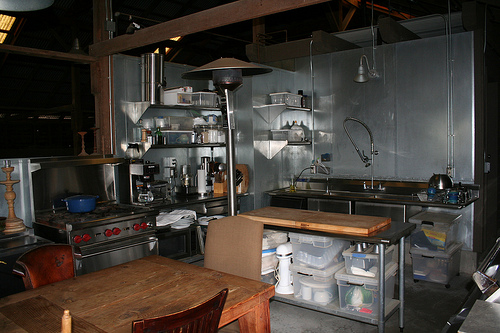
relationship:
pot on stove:
[58, 188, 107, 216] [50, 205, 148, 224]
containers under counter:
[265, 231, 379, 316] [254, 204, 412, 251]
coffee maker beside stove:
[124, 158, 168, 211] [50, 205, 148, 224]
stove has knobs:
[50, 205, 148, 224] [71, 221, 163, 245]